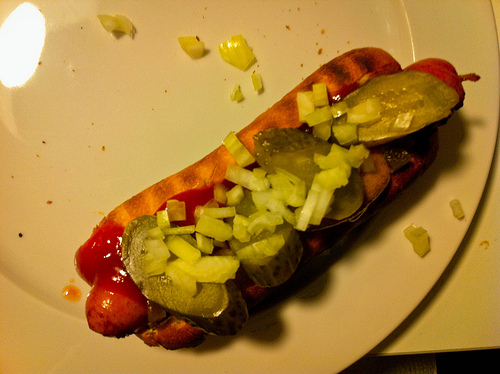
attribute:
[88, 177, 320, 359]
pickles — sliced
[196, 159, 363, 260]
onion — diced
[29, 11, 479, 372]
plate — round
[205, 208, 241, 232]
onion — diced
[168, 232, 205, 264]
onion — diced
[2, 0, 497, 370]
dish — white